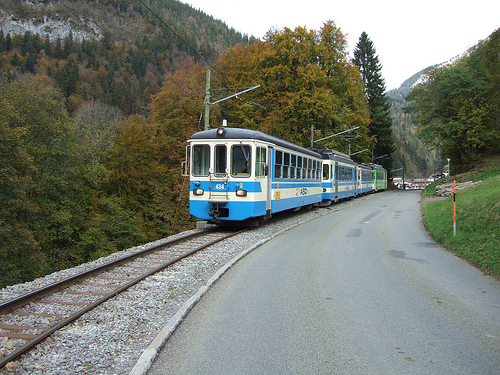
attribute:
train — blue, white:
[181, 127, 373, 231]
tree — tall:
[346, 30, 412, 189]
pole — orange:
[444, 164, 498, 248]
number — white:
[213, 182, 224, 192]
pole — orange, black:
[450, 178, 458, 239]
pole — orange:
[449, 177, 460, 235]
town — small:
[386, 176, 432, 196]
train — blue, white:
[192, 127, 375, 219]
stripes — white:
[249, 180, 325, 205]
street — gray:
[140, 188, 498, 373]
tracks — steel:
[0, 224, 244, 366]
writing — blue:
[298, 183, 308, 196]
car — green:
[370, 163, 390, 192]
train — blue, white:
[179, 115, 392, 233]